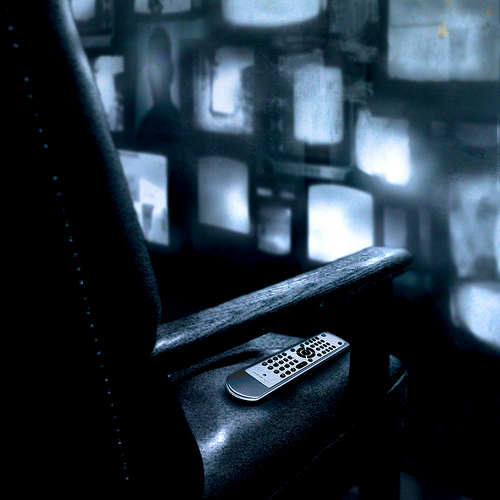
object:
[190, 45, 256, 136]
screens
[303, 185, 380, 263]
monitors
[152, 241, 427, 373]
armrest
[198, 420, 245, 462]
reflection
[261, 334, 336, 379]
buttons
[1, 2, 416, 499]
chair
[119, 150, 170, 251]
screen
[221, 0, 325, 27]
screen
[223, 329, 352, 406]
remote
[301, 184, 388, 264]
screen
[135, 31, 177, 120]
monitor screen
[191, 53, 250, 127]
monitor screen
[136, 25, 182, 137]
outline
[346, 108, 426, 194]
screen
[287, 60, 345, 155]
monitor screen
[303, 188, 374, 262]
monitor screen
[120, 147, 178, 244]
monitor screen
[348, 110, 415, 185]
screen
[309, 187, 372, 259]
screen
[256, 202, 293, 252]
screen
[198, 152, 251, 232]
screen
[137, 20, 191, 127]
screen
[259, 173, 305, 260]
monitor screen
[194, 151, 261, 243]
monitor screen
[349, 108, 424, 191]
monitor screen